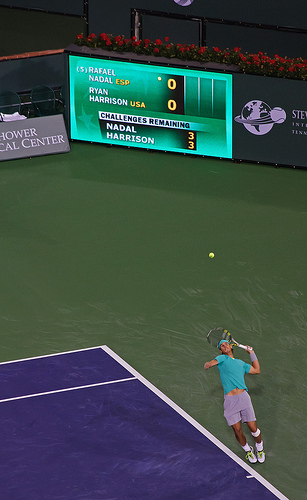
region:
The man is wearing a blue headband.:
[217, 338, 230, 349]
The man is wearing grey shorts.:
[219, 385, 255, 426]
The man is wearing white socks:
[239, 439, 264, 451]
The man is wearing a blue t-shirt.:
[212, 350, 249, 390]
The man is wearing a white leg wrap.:
[245, 424, 257, 434]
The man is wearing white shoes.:
[245, 447, 265, 463]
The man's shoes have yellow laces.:
[244, 449, 265, 458]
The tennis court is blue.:
[1, 342, 292, 499]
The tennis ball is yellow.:
[208, 251, 215, 260]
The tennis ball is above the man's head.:
[205, 246, 216, 260]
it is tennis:
[2, 305, 297, 498]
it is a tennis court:
[2, 306, 288, 491]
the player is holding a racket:
[1, 307, 285, 498]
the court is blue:
[83, 429, 167, 481]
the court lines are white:
[88, 324, 170, 409]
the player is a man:
[170, 322, 297, 495]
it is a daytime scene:
[1, 302, 293, 491]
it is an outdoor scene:
[1, 307, 299, 496]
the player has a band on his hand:
[240, 334, 261, 372]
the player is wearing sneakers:
[228, 423, 282, 489]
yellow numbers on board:
[183, 130, 200, 150]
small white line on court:
[240, 469, 267, 483]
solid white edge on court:
[98, 342, 162, 423]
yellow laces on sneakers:
[240, 449, 277, 463]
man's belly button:
[229, 384, 246, 400]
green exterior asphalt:
[162, 352, 204, 385]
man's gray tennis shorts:
[221, 392, 265, 430]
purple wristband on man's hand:
[243, 351, 267, 368]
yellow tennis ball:
[197, 241, 241, 291]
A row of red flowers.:
[69, 24, 303, 81]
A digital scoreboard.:
[68, 47, 233, 154]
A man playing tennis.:
[177, 314, 286, 471]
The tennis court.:
[47, 264, 172, 429]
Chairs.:
[1, 80, 70, 113]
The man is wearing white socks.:
[235, 435, 265, 464]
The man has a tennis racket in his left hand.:
[195, 318, 263, 379]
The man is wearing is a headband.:
[208, 332, 233, 359]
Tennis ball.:
[203, 248, 218, 265]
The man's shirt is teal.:
[208, 353, 257, 394]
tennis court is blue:
[1, 341, 293, 499]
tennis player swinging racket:
[193, 320, 266, 465]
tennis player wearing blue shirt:
[213, 352, 254, 393]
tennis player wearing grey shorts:
[216, 393, 258, 425]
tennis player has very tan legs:
[229, 419, 260, 446]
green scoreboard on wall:
[67, 52, 236, 167]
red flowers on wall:
[68, 24, 305, 85]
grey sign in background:
[0, 112, 76, 161]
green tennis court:
[0, 135, 305, 498]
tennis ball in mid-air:
[205, 243, 215, 260]